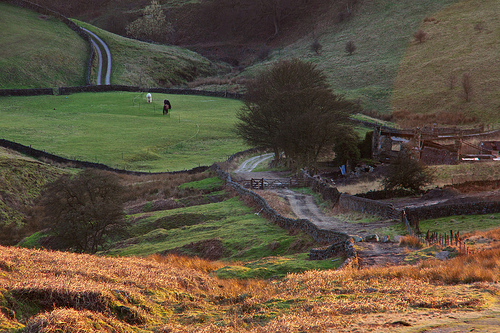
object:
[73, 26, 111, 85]
road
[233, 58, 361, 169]
tree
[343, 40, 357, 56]
tree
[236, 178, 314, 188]
fence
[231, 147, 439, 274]
road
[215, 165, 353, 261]
fence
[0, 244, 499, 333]
grass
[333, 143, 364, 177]
tree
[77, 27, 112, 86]
down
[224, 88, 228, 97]
post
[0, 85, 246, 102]
fence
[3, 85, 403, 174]
field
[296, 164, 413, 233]
wall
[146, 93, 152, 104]
horse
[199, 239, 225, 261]
rock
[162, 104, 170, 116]
horse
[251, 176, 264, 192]
gate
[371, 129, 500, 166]
building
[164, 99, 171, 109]
horse